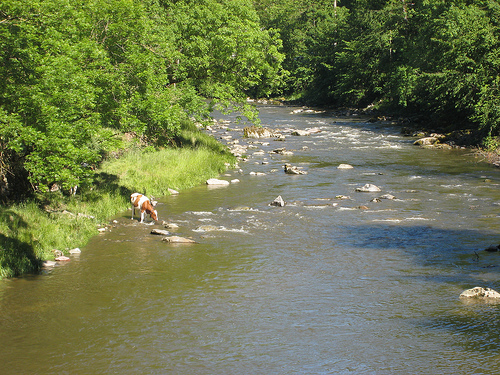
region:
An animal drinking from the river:
[129, 188, 159, 222]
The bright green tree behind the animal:
[12, 8, 241, 188]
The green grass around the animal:
[5, 125, 221, 289]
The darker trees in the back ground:
[276, 15, 493, 166]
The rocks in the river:
[234, 120, 493, 290]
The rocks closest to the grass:
[43, 169, 274, 288]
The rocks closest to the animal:
[123, 204, 248, 254]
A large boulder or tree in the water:
[222, 120, 323, 142]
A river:
[53, 101, 497, 367]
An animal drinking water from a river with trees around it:
[18, 23, 493, 361]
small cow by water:
[122, 188, 156, 227]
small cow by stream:
[115, 193, 160, 233]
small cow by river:
[119, 190, 158, 236]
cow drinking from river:
[117, 190, 164, 225]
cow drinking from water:
[120, 190, 160, 230]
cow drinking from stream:
[126, 195, 161, 223]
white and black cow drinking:
[128, 189, 157, 224]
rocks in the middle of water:
[238, 138, 335, 241]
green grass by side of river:
[0, 216, 90, 297]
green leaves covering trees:
[13, 3, 226, 159]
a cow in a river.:
[128, 182, 159, 225]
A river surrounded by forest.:
[0, 103, 498, 373]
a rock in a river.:
[446, 271, 499, 318]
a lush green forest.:
[254, 0, 496, 162]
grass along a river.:
[8, 138, 233, 286]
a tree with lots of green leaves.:
[2, 0, 297, 210]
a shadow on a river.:
[337, 208, 495, 293]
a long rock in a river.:
[284, 128, 331, 147]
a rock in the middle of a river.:
[269, 191, 299, 223]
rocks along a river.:
[31, 250, 86, 288]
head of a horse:
[149, 207, 166, 224]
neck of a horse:
[143, 200, 171, 219]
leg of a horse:
[135, 207, 152, 224]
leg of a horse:
[122, 205, 139, 222]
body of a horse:
[123, 187, 148, 207]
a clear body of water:
[28, 271, 309, 332]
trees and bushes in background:
[11, 44, 264, 193]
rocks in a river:
[219, 98, 405, 198]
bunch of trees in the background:
[330, 20, 475, 110]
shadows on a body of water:
[368, 217, 478, 284]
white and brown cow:
[126, 190, 158, 225]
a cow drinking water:
[126, 190, 156, 220]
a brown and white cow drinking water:
[125, 190, 156, 221]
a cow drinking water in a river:
[125, 190, 160, 227]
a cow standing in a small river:
[125, 186, 160, 223]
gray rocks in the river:
[270, 145, 496, 301]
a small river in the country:
[1, 98, 498, 373]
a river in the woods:
[1, 110, 498, 374]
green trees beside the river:
[1, 3, 292, 202]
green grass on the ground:
[125, 148, 205, 182]